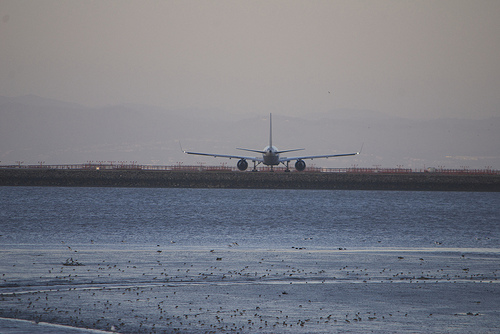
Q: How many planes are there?
A: One.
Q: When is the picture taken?
A: Daytime.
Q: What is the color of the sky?
A: Blue with clouds.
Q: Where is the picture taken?
A: Close to a lake.